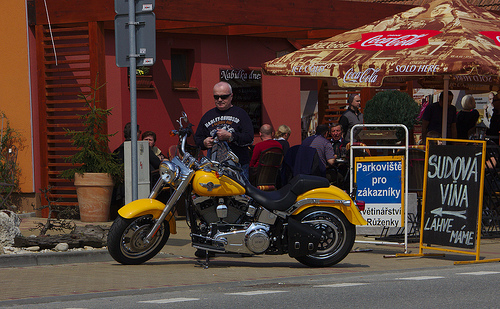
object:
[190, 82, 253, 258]
man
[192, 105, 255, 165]
shirt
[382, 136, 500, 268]
sign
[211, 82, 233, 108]
face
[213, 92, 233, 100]
glasses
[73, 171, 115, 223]
plant pot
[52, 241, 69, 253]
stone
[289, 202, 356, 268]
tire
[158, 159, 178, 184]
headlight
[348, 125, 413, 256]
street signs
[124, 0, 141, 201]
pole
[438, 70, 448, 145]
pole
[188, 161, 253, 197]
pants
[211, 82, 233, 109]
head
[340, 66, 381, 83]
logo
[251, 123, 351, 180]
people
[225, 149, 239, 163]
rearview mirror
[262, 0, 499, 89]
tent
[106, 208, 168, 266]
tire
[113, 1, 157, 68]
sign's back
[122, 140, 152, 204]
sign's back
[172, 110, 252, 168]
handalbars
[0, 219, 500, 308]
ground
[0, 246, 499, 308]
street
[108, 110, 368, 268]
motorcycle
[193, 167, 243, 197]
tank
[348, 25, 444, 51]
logo